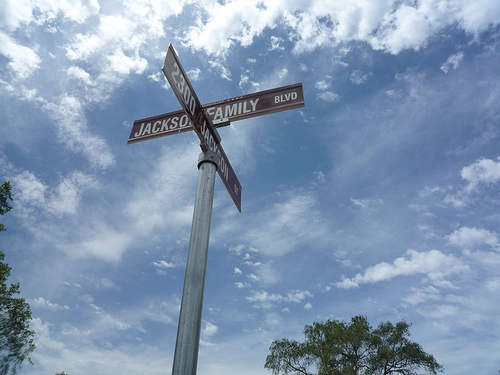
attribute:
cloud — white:
[336, 246, 466, 293]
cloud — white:
[457, 156, 496, 195]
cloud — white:
[369, 3, 496, 55]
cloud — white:
[0, 27, 53, 79]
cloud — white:
[249, 289, 315, 315]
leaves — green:
[265, 314, 450, 370]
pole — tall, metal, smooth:
[170, 153, 224, 373]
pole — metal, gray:
[171, 162, 218, 372]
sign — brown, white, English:
[127, 78, 308, 144]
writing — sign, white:
[132, 87, 295, 137]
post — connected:
[167, 161, 238, 335]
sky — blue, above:
[46, 49, 429, 281]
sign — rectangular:
[125, 63, 282, 195]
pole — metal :
[107, 92, 257, 364]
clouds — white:
[319, 18, 450, 60]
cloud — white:
[318, 185, 475, 358]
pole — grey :
[159, 142, 259, 371]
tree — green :
[266, 285, 429, 365]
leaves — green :
[364, 324, 450, 366]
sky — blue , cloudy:
[23, 31, 483, 320]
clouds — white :
[328, 22, 448, 134]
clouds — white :
[355, 20, 431, 77]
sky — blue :
[32, 26, 484, 353]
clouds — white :
[367, 206, 421, 291]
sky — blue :
[38, 33, 432, 341]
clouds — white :
[343, 21, 413, 58]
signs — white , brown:
[91, 30, 353, 240]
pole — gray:
[125, 78, 275, 373]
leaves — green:
[303, 316, 383, 359]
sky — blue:
[4, 4, 484, 367]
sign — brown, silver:
[123, 41, 299, 372]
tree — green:
[252, 311, 443, 371]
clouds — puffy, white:
[5, 6, 483, 371]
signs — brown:
[124, 46, 306, 208]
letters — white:
[207, 99, 255, 118]